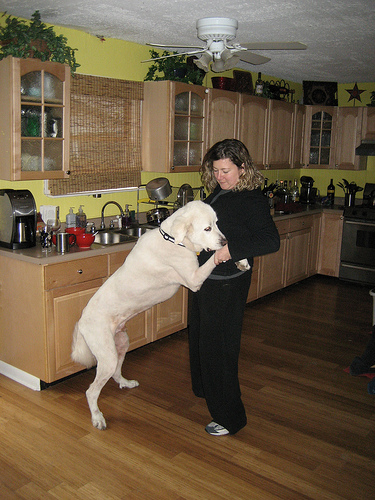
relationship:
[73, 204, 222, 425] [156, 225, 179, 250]
dog wearing collar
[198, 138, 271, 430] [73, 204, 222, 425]
woman holding dog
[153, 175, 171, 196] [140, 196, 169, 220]
pots inside of strainer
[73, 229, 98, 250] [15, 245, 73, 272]
bowls on top of counter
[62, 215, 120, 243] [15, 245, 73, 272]
mug on top of counter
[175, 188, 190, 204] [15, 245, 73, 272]
bucket on top of counter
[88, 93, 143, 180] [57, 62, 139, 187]
shade covers window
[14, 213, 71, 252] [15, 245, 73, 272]
coffee maker on top of counter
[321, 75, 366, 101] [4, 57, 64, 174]
star on top of cabinet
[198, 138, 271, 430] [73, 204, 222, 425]
woman with dog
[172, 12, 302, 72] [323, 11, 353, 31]
fan attached to ceiling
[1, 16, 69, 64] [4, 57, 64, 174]
plants on top of cabinet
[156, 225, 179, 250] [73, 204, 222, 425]
collar on dog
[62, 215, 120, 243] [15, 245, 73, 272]
mug on counter